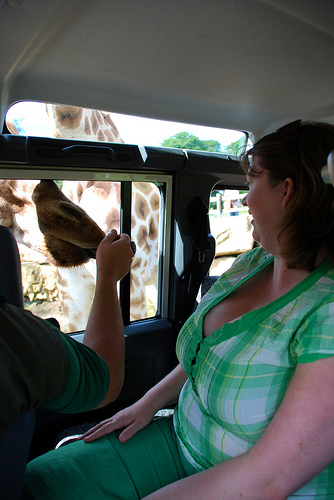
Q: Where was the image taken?
A: It was taken at the park.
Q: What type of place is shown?
A: It is a park.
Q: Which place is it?
A: It is a park.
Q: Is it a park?
A: Yes, it is a park.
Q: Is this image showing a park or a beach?
A: It is showing a park.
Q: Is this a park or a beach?
A: It is a park.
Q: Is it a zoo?
A: No, it is a park.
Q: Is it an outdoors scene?
A: Yes, it is outdoors.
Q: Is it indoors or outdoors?
A: It is outdoors.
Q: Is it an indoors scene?
A: No, it is outdoors.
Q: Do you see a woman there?
A: Yes, there is a woman.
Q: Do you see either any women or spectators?
A: Yes, there is a woman.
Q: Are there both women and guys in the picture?
A: No, there is a woman but no guys.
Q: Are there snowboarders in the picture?
A: No, there are no snowboarders.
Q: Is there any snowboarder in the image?
A: No, there are no snowboarders.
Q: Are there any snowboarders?
A: No, there are no snowboarders.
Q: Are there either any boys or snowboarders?
A: No, there are no snowboarders or boys.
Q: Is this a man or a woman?
A: This is a woman.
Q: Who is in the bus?
A: The woman is in the bus.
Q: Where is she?
A: The woman is in the bus.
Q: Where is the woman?
A: The woman is in the bus.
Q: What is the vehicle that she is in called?
A: The vehicle is a bus.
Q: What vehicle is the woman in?
A: The woman is in the bus.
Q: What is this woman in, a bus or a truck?
A: The woman is in a bus.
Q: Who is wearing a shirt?
A: The woman is wearing a shirt.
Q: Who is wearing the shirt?
A: The woman is wearing a shirt.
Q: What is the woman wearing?
A: The woman is wearing a shirt.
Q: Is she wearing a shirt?
A: Yes, the woman is wearing a shirt.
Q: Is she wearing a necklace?
A: No, the woman is wearing a shirt.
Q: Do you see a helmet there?
A: No, there are no helmets.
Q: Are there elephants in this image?
A: No, there are no elephants.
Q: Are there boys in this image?
A: No, there are no boys.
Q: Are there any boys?
A: No, there are no boys.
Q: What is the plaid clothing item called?
A: The clothing item is a shirt.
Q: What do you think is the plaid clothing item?
A: The clothing item is a shirt.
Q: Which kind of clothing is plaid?
A: The clothing is a shirt.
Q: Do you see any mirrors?
A: No, there are no mirrors.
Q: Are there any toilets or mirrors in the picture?
A: No, there are no mirrors or toilets.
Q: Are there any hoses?
A: No, there are no hoses.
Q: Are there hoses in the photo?
A: No, there are no hoses.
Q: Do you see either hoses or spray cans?
A: No, there are no hoses or spray cans.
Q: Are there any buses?
A: Yes, there is a bus.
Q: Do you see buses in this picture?
A: Yes, there is a bus.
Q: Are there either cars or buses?
A: Yes, there is a bus.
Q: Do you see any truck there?
A: No, there are no trucks.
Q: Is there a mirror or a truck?
A: No, there are no trucks or mirrors.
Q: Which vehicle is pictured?
A: The vehicle is a bus.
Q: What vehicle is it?
A: The vehicle is a bus.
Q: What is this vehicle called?
A: This is a bus.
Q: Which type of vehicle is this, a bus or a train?
A: This is a bus.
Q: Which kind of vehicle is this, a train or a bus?
A: This is a bus.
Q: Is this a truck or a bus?
A: This is a bus.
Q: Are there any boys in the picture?
A: No, there are no boys.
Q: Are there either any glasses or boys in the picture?
A: No, there are no boys or glasses.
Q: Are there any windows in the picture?
A: Yes, there is a window.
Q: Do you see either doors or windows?
A: Yes, there is a window.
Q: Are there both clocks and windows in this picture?
A: No, there is a window but no clocks.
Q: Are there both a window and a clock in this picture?
A: No, there is a window but no clocks.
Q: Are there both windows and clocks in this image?
A: No, there is a window but no clocks.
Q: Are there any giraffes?
A: Yes, there is a giraffe.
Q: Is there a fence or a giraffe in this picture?
A: Yes, there is a giraffe.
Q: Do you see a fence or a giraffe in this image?
A: Yes, there is a giraffe.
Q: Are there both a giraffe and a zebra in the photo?
A: No, there is a giraffe but no zebras.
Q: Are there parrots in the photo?
A: No, there are no parrots.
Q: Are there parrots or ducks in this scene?
A: No, there are no parrots or ducks.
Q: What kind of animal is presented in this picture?
A: The animal is a giraffe.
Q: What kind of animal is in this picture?
A: The animal is a giraffe.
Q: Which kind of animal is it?
A: The animal is a giraffe.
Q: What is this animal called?
A: This is a giraffe.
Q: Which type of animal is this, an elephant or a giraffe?
A: This is a giraffe.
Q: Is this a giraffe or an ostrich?
A: This is a giraffe.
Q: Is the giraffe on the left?
A: Yes, the giraffe is on the left of the image.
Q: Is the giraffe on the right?
A: No, the giraffe is on the left of the image.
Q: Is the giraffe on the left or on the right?
A: The giraffe is on the left of the image.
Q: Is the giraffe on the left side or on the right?
A: The giraffe is on the left of the image.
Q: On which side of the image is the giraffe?
A: The giraffe is on the left of the image.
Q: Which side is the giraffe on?
A: The giraffe is on the left of the image.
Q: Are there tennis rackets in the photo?
A: No, there are no tennis rackets.